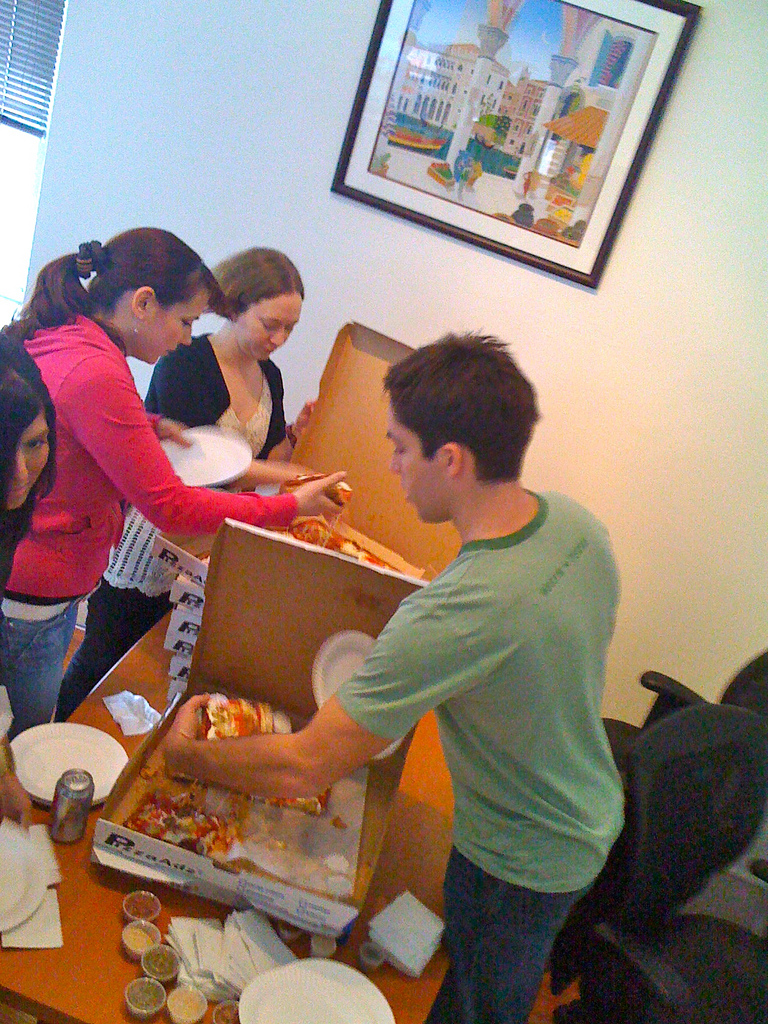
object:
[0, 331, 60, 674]
woman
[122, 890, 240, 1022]
containers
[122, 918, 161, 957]
sauce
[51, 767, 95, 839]
can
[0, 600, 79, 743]
jeans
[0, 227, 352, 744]
girl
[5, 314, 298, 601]
sweatshirt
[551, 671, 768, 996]
chair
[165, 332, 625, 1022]
boy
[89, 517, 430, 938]
box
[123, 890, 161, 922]
container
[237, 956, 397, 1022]
paper plates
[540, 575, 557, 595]
letter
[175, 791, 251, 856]
pieces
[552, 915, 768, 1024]
office chair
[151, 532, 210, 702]
pizza boxes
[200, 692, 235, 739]
piece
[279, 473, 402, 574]
pizza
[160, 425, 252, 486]
plate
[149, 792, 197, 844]
slice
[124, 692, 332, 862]
pizza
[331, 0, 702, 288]
art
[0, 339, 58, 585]
hair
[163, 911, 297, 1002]
napkin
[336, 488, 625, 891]
shirt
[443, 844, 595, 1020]
pant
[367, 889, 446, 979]
napkin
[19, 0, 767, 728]
wall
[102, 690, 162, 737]
napkin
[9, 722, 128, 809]
plate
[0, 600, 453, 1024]
table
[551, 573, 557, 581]
letter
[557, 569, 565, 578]
letter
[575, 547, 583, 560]
letter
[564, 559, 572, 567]
letter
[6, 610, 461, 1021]
table